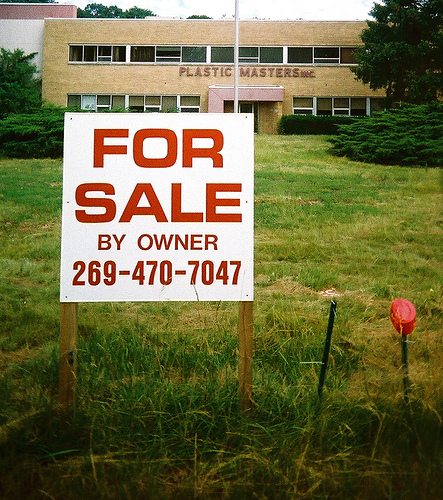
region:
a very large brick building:
[29, 9, 403, 141]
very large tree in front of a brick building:
[343, 0, 432, 174]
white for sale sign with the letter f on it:
[35, 105, 267, 339]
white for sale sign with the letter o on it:
[31, 106, 262, 343]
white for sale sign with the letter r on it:
[36, 78, 272, 318]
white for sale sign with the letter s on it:
[44, 96, 275, 325]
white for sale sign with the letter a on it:
[50, 107, 269, 322]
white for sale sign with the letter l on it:
[52, 92, 270, 320]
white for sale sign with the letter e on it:
[30, 68, 283, 323]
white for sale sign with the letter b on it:
[32, 104, 259, 340]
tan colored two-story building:
[35, 7, 409, 140]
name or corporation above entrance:
[171, 49, 324, 80]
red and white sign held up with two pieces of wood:
[41, 100, 259, 437]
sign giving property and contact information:
[56, 111, 261, 303]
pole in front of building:
[215, 0, 265, 109]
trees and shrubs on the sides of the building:
[2, 4, 429, 160]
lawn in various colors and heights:
[256, 132, 394, 278]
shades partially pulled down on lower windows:
[63, 87, 364, 116]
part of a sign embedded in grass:
[309, 271, 349, 306]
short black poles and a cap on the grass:
[301, 243, 425, 464]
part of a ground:
[348, 173, 401, 210]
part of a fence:
[294, 349, 328, 391]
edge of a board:
[178, 295, 201, 305]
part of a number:
[144, 261, 178, 286]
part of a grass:
[181, 438, 219, 480]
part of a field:
[199, 413, 241, 450]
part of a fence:
[153, 303, 220, 382]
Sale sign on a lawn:
[61, 111, 258, 412]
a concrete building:
[7, 0, 401, 134]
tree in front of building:
[358, 3, 442, 109]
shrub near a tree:
[346, 109, 442, 165]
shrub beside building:
[6, 108, 67, 152]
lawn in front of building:
[10, 134, 441, 451]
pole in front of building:
[232, 0, 240, 115]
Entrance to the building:
[208, 86, 281, 137]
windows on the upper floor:
[67, 42, 373, 69]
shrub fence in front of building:
[277, 113, 350, 131]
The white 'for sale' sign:
[55, 109, 259, 305]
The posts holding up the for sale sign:
[53, 302, 259, 419]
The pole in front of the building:
[229, 0, 241, 118]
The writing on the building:
[174, 63, 316, 80]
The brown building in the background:
[39, 14, 442, 147]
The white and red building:
[0, 1, 77, 76]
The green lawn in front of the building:
[0, 132, 440, 499]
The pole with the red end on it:
[388, 294, 420, 415]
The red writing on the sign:
[72, 123, 243, 289]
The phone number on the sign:
[69, 259, 243, 288]